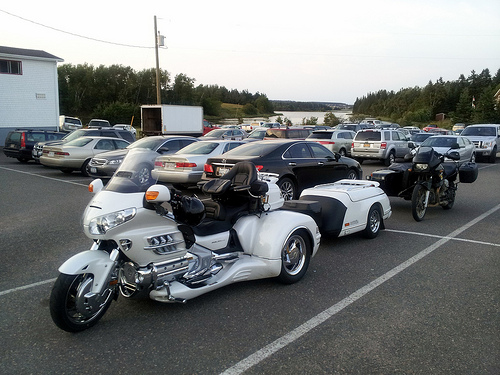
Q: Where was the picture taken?
A: It was taken at the parking lot.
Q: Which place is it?
A: It is a parking lot.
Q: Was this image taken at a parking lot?
A: Yes, it was taken in a parking lot.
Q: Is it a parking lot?
A: Yes, it is a parking lot.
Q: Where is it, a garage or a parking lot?
A: It is a parking lot.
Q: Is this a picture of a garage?
A: No, the picture is showing a parking lot.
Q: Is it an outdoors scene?
A: Yes, it is outdoors.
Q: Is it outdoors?
A: Yes, it is outdoors.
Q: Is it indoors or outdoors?
A: It is outdoors.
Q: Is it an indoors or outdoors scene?
A: It is outdoors.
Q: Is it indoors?
A: No, it is outdoors.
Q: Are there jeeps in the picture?
A: No, there are no jeeps.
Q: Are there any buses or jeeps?
A: No, there are no jeeps or buses.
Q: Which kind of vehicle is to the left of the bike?
A: The vehicle is a car.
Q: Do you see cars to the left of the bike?
A: Yes, there is a car to the left of the bike.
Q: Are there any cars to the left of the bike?
A: Yes, there is a car to the left of the bike.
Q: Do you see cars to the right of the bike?
A: No, the car is to the left of the bike.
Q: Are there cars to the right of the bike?
A: No, the car is to the left of the bike.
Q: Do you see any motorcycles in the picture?
A: Yes, there is a motorcycle.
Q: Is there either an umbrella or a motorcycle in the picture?
A: Yes, there is a motorcycle.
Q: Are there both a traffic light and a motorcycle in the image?
A: No, there is a motorcycle but no traffic lights.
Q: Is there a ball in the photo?
A: No, there are no balls.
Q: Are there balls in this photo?
A: No, there are no balls.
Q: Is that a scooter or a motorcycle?
A: That is a motorcycle.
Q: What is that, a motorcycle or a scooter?
A: That is a motorcycle.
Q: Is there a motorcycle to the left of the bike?
A: Yes, there is a motorcycle to the left of the bike.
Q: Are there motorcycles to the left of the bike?
A: Yes, there is a motorcycle to the left of the bike.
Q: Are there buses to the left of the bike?
A: No, there is a motorcycle to the left of the bike.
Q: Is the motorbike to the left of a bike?
A: Yes, the motorbike is to the left of a bike.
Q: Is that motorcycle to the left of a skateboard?
A: No, the motorcycle is to the left of a bike.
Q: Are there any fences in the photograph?
A: No, there are no fences.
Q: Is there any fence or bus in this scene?
A: No, there are no fences or buses.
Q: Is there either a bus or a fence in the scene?
A: No, there are no fences or buses.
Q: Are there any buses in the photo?
A: No, there are no buses.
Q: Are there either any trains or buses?
A: No, there are no buses or trains.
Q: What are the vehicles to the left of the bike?
A: The vehicles are cars.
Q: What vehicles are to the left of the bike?
A: The vehicles are cars.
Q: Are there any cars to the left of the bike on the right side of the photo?
A: Yes, there are cars to the left of the bike.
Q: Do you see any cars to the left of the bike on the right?
A: Yes, there are cars to the left of the bike.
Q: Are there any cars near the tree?
A: Yes, there are cars near the tree.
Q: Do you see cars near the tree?
A: Yes, there are cars near the tree.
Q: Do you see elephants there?
A: No, there are no elephants.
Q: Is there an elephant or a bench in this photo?
A: No, there are no elephants or benches.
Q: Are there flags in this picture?
A: No, there are no flags.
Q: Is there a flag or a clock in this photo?
A: No, there are no flags or clocks.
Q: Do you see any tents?
A: No, there are no tents.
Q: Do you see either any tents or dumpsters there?
A: No, there are no tents or dumpsters.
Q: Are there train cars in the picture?
A: No, there are no train cars.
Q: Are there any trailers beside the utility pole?
A: Yes, there is a trailer beside the utility pole.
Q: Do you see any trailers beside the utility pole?
A: Yes, there is a trailer beside the utility pole.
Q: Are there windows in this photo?
A: Yes, there is a window.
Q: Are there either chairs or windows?
A: Yes, there is a window.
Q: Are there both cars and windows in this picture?
A: Yes, there are both a window and a car.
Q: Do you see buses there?
A: No, there are no buses.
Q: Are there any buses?
A: No, there are no buses.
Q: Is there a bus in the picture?
A: No, there are no buses.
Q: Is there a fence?
A: No, there are no fences.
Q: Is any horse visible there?
A: No, there are no horses.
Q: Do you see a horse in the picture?
A: No, there are no horses.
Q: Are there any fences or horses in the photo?
A: No, there are no horses or fences.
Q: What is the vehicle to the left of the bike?
A: The vehicle is a trailer.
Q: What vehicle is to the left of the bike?
A: The vehicle is a trailer.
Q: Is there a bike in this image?
A: Yes, there is a bike.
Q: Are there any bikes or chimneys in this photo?
A: Yes, there is a bike.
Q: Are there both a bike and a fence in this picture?
A: No, there is a bike but no fences.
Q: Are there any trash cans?
A: No, there are no trash cans.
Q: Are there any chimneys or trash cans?
A: No, there are no trash cans or chimneys.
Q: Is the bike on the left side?
A: No, the bike is on the right of the image.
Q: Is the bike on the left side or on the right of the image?
A: The bike is on the right of the image.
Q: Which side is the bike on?
A: The bike is on the right of the image.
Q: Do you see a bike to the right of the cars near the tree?
A: Yes, there is a bike to the right of the cars.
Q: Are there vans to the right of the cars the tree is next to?
A: No, there is a bike to the right of the cars.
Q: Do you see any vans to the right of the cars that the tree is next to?
A: No, there is a bike to the right of the cars.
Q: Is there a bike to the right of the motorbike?
A: Yes, there is a bike to the right of the motorbike.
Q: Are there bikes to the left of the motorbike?
A: No, the bike is to the right of the motorbike.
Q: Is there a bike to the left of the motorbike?
A: No, the bike is to the right of the motorbike.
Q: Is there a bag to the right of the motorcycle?
A: No, there is a bike to the right of the motorcycle.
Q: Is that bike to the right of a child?
A: No, the bike is to the right of the motorcycle.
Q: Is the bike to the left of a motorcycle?
A: No, the bike is to the right of a motorcycle.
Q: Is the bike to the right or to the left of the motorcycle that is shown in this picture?
A: The bike is to the right of the motorcycle.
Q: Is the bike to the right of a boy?
A: No, the bike is to the right of the car.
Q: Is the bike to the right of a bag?
A: No, the bike is to the right of the trailer.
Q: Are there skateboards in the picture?
A: No, there are no skateboards.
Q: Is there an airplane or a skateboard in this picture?
A: No, there are no skateboards or airplanes.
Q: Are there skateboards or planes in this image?
A: No, there are no skateboards or planes.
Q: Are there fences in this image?
A: No, there are no fences.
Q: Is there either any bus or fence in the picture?
A: No, there are no fences or buses.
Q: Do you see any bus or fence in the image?
A: No, there are no fences or buses.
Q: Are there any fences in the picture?
A: No, there are no fences.